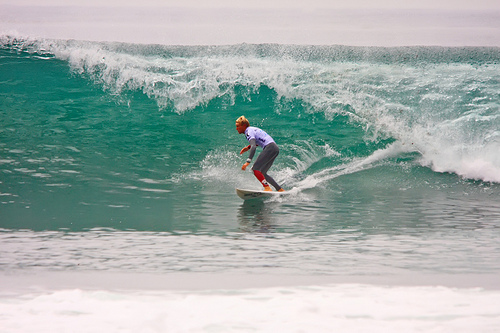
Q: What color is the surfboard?
A: White.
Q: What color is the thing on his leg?
A: Red.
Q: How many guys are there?
A: One.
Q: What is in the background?
A: The sky.